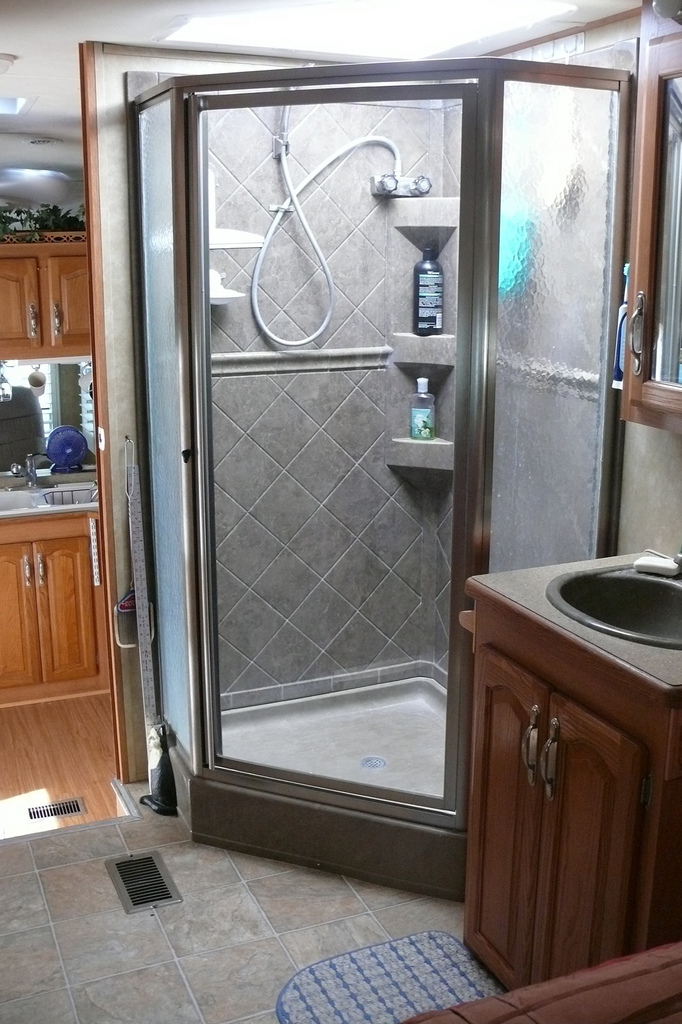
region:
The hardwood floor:
[0, 685, 150, 840]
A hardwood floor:
[0, 691, 138, 849]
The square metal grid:
[20, 789, 93, 821]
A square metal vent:
[108, 840, 186, 910]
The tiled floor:
[3, 775, 468, 1020]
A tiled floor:
[2, 779, 469, 1022]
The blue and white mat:
[271, 923, 481, 1022]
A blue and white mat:
[261, 922, 490, 1019]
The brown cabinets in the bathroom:
[457, 601, 611, 997]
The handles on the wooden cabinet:
[504, 698, 572, 791]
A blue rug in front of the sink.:
[271, 929, 499, 1020]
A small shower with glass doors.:
[122, 54, 626, 898]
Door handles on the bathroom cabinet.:
[517, 699, 559, 798]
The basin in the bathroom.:
[543, 562, 675, 644]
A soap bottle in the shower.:
[405, 372, 430, 438]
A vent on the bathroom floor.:
[103, 848, 178, 912]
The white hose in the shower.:
[248, 104, 399, 343]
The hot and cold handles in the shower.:
[366, 172, 428, 195]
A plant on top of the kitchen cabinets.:
[0, 199, 83, 237]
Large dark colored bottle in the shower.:
[411, 246, 443, 333]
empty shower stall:
[126, 57, 631, 904]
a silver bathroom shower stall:
[121, 60, 638, 901]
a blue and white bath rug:
[272, 924, 497, 1023]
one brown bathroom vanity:
[461, 545, 680, 1002]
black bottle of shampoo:
[409, 240, 451, 336]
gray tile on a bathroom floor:
[0, 814, 465, 1021]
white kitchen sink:
[4, 457, 97, 514]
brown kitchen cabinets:
[2, 508, 110, 701]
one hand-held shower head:
[245, 59, 436, 350]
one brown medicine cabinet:
[619, 2, 680, 427]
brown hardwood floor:
[0, 692, 110, 853]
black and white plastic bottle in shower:
[412, 242, 444, 335]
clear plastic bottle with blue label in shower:
[407, 375, 433, 436]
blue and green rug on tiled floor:
[272, 930, 500, 1022]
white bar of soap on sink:
[633, 555, 677, 575]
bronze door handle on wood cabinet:
[536, 715, 557, 796]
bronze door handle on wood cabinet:
[518, 706, 539, 787]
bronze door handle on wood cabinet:
[33, 556, 48, 589]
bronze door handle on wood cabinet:
[22, 555, 29, 588]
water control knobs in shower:
[367, 169, 429, 196]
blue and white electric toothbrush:
[611, 261, 631, 382]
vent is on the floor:
[98, 832, 206, 935]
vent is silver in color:
[97, 835, 213, 919]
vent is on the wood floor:
[19, 786, 100, 825]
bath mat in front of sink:
[253, 880, 487, 1022]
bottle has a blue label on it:
[396, 374, 442, 450]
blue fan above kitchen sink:
[31, 413, 106, 477]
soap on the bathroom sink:
[629, 542, 672, 597]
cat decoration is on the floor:
[115, 709, 215, 832]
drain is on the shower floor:
[328, 723, 418, 783]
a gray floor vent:
[106, 848, 186, 914]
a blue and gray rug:
[268, 927, 491, 1022]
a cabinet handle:
[532, 715, 561, 798]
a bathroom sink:
[549, 550, 680, 643]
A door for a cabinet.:
[42, 247, 96, 364]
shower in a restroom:
[124, 56, 620, 895]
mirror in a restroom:
[623, 13, 677, 439]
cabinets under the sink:
[442, 639, 652, 1001]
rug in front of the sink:
[257, 929, 506, 1018]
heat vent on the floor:
[101, 844, 182, 921]